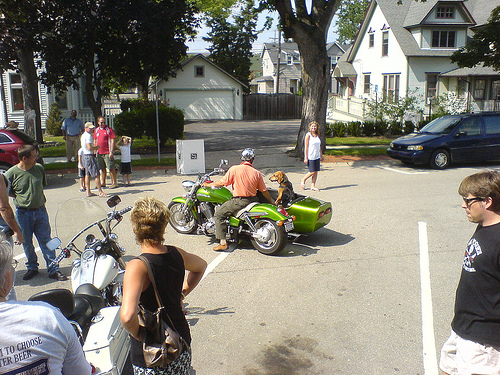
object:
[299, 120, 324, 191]
woman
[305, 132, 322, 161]
tank top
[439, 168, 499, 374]
man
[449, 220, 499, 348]
shirt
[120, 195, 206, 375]
woman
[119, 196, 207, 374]
purse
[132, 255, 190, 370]
shoulder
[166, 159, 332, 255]
motorcyle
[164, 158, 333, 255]
side car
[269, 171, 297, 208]
dog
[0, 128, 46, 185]
car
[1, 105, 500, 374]
street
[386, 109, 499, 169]
van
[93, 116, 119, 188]
man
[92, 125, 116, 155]
shirt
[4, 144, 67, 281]
man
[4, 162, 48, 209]
shirt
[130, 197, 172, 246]
hair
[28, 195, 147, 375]
motorcyle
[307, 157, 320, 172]
shorts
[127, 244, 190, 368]
top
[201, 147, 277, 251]
man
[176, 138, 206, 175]
box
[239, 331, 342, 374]
spot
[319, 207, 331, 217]
lights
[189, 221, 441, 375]
stripes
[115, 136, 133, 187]
kid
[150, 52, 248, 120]
garage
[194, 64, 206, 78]
window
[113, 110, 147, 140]
bush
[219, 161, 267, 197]
shirt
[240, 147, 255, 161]
helmet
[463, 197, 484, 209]
sunglasses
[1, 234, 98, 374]
person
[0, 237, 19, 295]
hair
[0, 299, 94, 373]
shirt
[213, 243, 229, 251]
shoes